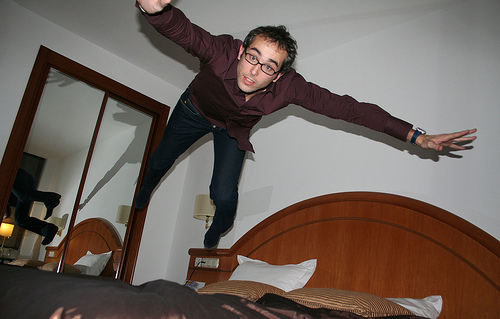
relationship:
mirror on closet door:
[0, 44, 170, 283] [12, 52, 139, 281]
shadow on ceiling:
[40, 67, 142, 204] [180, 0, 479, 58]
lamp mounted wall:
[192, 193, 216, 230] [165, 1, 499, 285]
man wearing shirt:
[135, 0, 477, 251] [138, 3, 414, 155]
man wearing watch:
[135, 0, 477, 251] [410, 121, 425, 151]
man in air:
[135, 0, 477, 251] [376, 43, 456, 79]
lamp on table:
[193, 194, 216, 230] [2, 251, 14, 266]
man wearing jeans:
[123, 1, 482, 280] [142, 86, 246, 233]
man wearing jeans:
[123, 1, 482, 280] [141, 124, 248, 241]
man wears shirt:
[123, 1, 482, 280] [144, 9, 411, 140]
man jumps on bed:
[135, 0, 477, 251] [101, 260, 318, 317]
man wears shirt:
[135, 0, 477, 251] [138, 3, 414, 155]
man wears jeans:
[135, 0, 477, 251] [127, 80, 254, 240]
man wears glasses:
[135, 0, 477, 251] [238, 42, 283, 74]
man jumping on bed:
[123, 1, 482, 280] [0, 185, 499, 316]